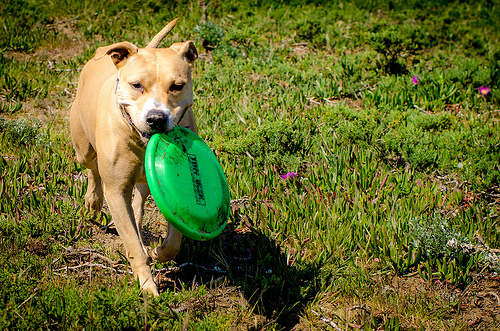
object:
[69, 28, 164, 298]
dog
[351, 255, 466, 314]
ground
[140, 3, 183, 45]
tail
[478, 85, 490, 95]
flower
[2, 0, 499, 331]
field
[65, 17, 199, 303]
dog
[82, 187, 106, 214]
paw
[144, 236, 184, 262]
paw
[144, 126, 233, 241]
frisbee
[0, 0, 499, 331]
scene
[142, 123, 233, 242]
disc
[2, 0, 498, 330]
lawn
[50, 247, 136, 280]
twig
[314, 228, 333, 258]
blade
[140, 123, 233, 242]
toy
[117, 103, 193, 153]
mouth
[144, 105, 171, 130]
nose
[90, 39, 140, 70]
ear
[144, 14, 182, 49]
tail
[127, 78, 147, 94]
eyes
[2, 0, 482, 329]
grass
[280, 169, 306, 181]
flowers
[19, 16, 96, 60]
patch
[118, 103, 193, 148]
mouth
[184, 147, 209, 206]
writing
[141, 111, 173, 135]
nose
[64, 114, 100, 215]
legs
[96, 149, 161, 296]
legs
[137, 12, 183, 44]
tail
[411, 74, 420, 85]
flower